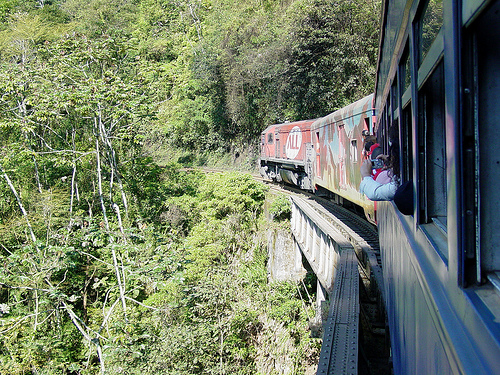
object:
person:
[361, 125, 401, 201]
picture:
[0, 0, 500, 375]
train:
[258, 0, 499, 375]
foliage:
[228, 198, 286, 213]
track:
[315, 194, 379, 249]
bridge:
[261, 182, 411, 374]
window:
[425, 83, 447, 231]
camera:
[370, 159, 384, 169]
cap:
[371, 146, 383, 159]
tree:
[305, 30, 349, 96]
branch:
[63, 59, 79, 81]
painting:
[340, 106, 355, 125]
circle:
[285, 126, 302, 159]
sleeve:
[360, 177, 399, 202]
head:
[371, 146, 383, 160]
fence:
[288, 193, 359, 374]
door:
[457, 58, 500, 325]